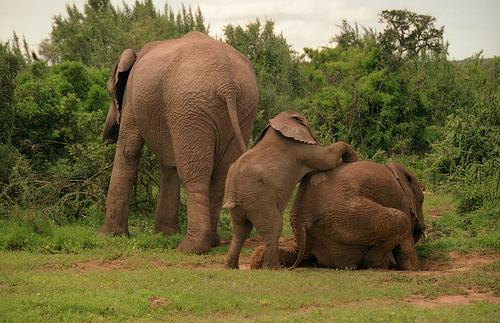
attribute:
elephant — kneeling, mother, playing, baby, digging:
[288, 158, 428, 270]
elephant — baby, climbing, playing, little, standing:
[220, 109, 360, 269]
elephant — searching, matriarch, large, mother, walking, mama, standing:
[100, 28, 263, 255]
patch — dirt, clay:
[411, 288, 499, 307]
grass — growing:
[3, 222, 498, 321]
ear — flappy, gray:
[271, 115, 316, 145]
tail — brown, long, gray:
[223, 95, 246, 154]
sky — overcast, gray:
[2, 0, 500, 62]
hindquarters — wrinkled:
[171, 79, 262, 156]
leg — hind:
[248, 207, 284, 270]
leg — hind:
[224, 208, 253, 268]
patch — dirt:
[72, 258, 124, 271]